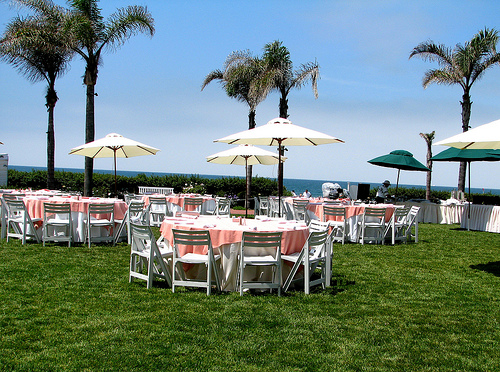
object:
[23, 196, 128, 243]
tables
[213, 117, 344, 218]
parsol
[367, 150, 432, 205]
parasol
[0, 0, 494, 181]
sky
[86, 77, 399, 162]
clouds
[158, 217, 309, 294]
table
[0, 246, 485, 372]
grass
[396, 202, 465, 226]
tablecloth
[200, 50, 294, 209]
palm tree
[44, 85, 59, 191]
trunk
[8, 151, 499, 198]
water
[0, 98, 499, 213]
background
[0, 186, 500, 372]
ground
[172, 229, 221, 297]
chair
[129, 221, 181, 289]
chairs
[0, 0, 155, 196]
palm trees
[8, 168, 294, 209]
hedge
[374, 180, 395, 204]
man